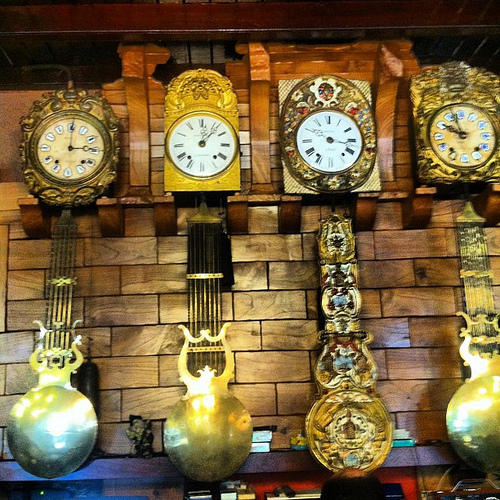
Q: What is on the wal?
A: Clocks.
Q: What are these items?
A: Clocks.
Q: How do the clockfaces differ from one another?
A: They all have a different time.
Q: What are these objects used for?
A: To tell time.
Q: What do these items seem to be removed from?
A: Grandfather clocks.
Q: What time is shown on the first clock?
A: 3:00.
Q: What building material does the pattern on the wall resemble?
A: Brick.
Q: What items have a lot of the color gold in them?
A: The clocks.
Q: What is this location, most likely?
A: Store.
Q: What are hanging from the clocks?
A: Pendulums.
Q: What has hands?
A: Clocks.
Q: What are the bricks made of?
A: Wood.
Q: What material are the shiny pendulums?
A: Brass metal.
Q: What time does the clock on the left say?
A: 3:00.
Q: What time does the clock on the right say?
A: 9:57.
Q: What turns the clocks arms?
A: Gears.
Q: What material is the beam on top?
A: Wood.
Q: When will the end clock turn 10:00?
A: 3 minutes.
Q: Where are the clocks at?
A: Wall.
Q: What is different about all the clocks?
A: The time.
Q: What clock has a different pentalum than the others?
A: 3rd.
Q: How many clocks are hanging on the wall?
A: 4.